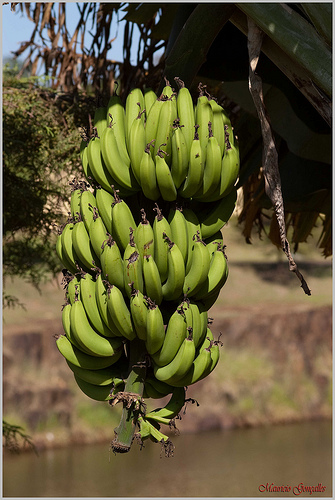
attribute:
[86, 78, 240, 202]
banana bunch — bunched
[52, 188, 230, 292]
banana bunch — bunched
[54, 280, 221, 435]
banana bunch — bunched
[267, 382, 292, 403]
bush — green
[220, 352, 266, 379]
bush — green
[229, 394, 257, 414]
bush — green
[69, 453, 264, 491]
river — muddy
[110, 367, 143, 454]
stem — dark green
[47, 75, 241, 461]
bananas — growing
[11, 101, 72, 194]
leaves — small, green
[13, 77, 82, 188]
bush — green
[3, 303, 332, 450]
river bank — steep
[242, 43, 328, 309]
leaf — long, dried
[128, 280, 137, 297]
stem — brown, dry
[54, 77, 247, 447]
bananas — green, hanging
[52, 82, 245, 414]
bananas — green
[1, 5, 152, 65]
sky — blue, cloudless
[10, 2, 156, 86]
leaves — brown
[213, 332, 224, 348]
stem — brown, dry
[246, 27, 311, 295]
leaf — long, thin, dead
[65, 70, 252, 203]
bananas — green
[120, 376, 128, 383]
stem — dry, brown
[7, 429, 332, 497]
river — muddy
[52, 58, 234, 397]
bananas — green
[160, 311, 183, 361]
banana — green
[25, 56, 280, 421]
bananas — green, bunch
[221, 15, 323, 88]
tree — banana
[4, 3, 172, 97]
leaves — hanging down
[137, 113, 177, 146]
bananas — green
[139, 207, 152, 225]
stem — brown, dry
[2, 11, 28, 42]
sky — blue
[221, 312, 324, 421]
bank — steep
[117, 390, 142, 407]
stem — dry, brown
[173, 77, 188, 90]
stem — dry, brown